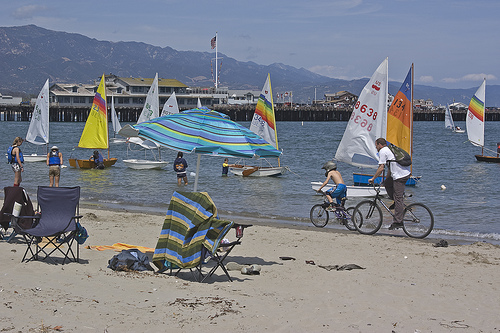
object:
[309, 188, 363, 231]
bikes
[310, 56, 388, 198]
boats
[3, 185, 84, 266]
chair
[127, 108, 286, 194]
umbrella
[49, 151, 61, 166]
vest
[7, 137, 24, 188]
people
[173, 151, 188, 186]
girl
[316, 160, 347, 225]
boy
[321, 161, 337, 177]
helmet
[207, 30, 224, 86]
flag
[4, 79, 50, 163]
sailboats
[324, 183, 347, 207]
short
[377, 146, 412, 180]
t-shirt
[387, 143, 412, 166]
backpack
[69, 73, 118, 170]
boat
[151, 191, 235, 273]
towel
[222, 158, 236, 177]
person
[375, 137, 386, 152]
head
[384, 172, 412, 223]
pants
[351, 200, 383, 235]
tire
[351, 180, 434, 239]
bicycle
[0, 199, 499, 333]
beach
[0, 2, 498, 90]
sky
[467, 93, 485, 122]
rainbow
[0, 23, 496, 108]
montains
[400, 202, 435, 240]
wheel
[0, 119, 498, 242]
water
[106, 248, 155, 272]
towel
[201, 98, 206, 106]
windows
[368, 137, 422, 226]
person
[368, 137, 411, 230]
man